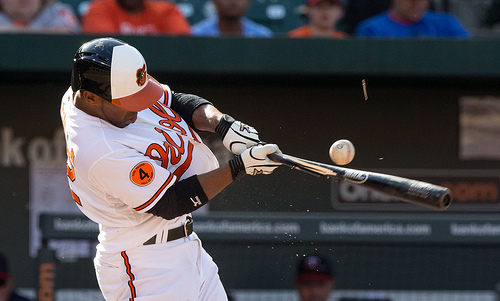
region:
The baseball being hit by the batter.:
[332, 139, 356, 161]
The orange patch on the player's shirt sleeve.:
[127, 160, 158, 186]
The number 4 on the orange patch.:
[136, 162, 149, 180]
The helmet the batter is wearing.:
[67, 43, 163, 117]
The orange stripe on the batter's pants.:
[119, 255, 143, 300]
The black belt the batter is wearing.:
[134, 215, 205, 246]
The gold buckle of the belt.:
[183, 213, 195, 241]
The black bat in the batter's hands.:
[280, 141, 450, 223]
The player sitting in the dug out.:
[282, 230, 347, 299]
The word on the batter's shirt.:
[145, 105, 202, 173]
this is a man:
[41, 20, 256, 297]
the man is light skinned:
[205, 172, 221, 185]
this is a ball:
[326, 133, 363, 163]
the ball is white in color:
[328, 132, 350, 154]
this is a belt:
[165, 224, 201, 244]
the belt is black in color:
[171, 227, 179, 241]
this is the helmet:
[78, 39, 140, 102]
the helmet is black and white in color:
[79, 49, 139, 83]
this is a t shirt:
[71, 131, 121, 223]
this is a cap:
[297, 250, 331, 278]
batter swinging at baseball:
[50, 25, 468, 291]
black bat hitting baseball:
[268, 122, 460, 212]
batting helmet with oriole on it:
[55, 35, 164, 111]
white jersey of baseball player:
[52, 94, 226, 229]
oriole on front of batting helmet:
[138, 66, 152, 83]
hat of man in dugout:
[286, 248, 334, 274]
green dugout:
[1, 28, 498, 289]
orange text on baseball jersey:
[136, 105, 213, 178]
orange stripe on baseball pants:
[119, 243, 141, 300]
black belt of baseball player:
[118, 220, 207, 238]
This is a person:
[46, 31, 314, 288]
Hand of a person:
[96, 140, 287, 221]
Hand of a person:
[159, 76, 277, 151]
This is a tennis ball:
[329, 129, 362, 173]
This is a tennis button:
[237, 135, 467, 226]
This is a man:
[52, 3, 294, 298]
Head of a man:
[57, 28, 185, 146]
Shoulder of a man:
[60, 105, 137, 169]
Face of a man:
[120, 79, 159, 134]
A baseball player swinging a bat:
[58, 38, 451, 299]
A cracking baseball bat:
[253, 138, 452, 211]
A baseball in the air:
[325, 137, 357, 165]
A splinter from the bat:
[359, 79, 370, 101]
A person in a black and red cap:
[293, 250, 337, 299]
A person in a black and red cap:
[0, 248, 29, 300]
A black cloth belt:
[145, 213, 196, 244]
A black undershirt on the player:
[145, 89, 213, 221]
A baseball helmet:
[66, 36, 161, 111]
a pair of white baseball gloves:
[218, 113, 280, 181]